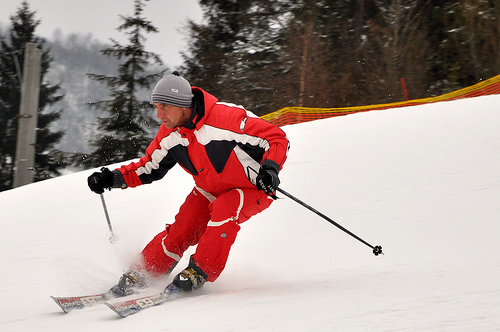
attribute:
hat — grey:
[147, 71, 194, 107]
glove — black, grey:
[251, 158, 288, 193]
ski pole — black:
[96, 195, 123, 244]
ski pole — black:
[280, 184, 391, 261]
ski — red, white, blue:
[52, 287, 107, 310]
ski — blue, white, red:
[104, 294, 163, 314]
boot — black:
[168, 259, 207, 295]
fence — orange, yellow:
[279, 69, 498, 122]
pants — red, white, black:
[142, 195, 274, 279]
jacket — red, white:
[115, 92, 307, 201]